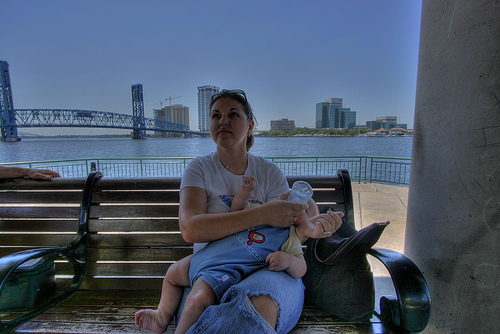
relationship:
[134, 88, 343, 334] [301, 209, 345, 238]
lady has fingers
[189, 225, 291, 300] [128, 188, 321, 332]
dress for baby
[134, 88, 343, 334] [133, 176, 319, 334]
lady feeding baby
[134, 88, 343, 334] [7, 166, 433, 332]
lady sitting on bench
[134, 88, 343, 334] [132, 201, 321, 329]
lady feeding baby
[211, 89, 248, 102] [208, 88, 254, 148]
glasses on head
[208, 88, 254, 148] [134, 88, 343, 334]
head of lady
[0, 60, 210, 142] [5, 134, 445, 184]
bridge over water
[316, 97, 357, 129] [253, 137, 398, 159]
building across water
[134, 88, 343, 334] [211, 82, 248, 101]
lady has glasses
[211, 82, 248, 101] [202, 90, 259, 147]
glasses on head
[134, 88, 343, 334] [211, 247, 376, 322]
lady wearing jeans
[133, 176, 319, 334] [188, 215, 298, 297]
baby wearing dress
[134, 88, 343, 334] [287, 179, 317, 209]
lady holds baby bottle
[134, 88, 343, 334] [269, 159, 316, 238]
lady holding baby bottle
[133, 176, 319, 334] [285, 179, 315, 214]
baby having bottle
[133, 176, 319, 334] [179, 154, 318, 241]
baby in arms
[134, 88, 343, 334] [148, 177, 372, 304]
lady holds baby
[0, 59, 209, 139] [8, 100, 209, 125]
bridge on background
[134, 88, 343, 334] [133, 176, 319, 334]
lady feeds baby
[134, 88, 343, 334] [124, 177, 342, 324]
lady holds baby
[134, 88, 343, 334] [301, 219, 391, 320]
lady has purse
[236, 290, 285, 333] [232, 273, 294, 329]
hole has hole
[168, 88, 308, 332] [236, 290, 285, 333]
lady has hole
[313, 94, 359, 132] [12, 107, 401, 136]
building on background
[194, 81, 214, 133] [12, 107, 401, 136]
building on background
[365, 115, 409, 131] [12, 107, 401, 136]
building on background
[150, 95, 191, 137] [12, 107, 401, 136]
building on background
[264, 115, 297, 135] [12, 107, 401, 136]
building on background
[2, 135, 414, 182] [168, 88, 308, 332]
water behind lady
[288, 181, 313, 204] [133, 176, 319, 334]
baby bottle in baby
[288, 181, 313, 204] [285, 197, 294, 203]
baby bottle in mouth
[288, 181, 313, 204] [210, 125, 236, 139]
baby bottle in mouth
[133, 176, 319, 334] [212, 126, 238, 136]
baby in mouth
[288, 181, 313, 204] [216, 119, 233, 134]
baby bottle in mouth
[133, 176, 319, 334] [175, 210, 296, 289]
baby wearing shirt